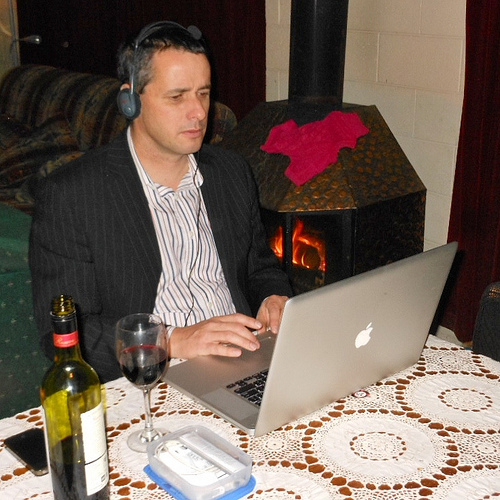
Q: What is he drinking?
A: Red wine.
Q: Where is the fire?
A: In the fireplace.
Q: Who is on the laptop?
A: The man.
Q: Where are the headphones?
A: On the man's head.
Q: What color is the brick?
A: White.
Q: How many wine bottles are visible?
A: One.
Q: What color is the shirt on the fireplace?
A: Red.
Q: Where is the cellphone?
A: On the table.